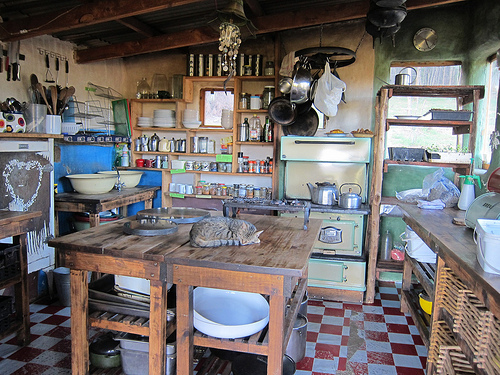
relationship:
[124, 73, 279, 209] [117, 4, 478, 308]
shelves against wall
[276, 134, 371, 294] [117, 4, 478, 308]
stove against wall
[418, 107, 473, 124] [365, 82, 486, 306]
pan on shelf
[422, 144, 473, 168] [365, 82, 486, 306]
container on shelf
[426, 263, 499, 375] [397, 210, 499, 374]
baskets in counter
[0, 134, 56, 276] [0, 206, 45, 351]
cabinet near table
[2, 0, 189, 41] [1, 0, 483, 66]
beam on ceiling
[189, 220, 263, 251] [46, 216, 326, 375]
cat on table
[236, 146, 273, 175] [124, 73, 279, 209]
spices on shelves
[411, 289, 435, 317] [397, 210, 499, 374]
bowl in counter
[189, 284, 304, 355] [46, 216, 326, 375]
shelf on table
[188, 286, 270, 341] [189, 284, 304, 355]
bowl on shelf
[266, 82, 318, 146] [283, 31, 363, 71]
pans on rack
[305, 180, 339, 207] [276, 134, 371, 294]
kettle on stove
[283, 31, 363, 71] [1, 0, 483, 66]
rack on ceiling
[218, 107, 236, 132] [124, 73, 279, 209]
bowls on shelves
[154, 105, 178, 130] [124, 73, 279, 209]
plates on shelves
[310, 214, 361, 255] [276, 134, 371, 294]
door on stove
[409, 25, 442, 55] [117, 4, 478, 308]
clock on wall